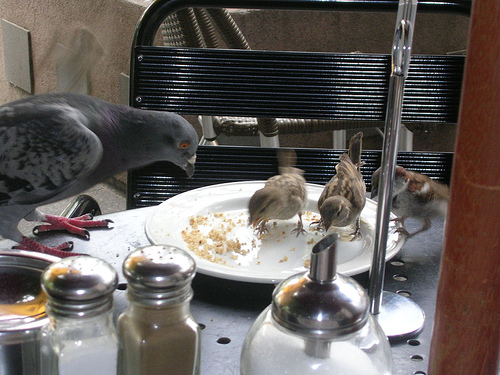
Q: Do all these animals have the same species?
A: Yes, all the animals are birds.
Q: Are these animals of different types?
A: No, all the animals are birds.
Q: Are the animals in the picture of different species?
A: No, all the animals are birds.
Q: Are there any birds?
A: Yes, there are birds.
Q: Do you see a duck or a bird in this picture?
A: Yes, there are birds.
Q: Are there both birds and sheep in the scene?
A: No, there are birds but no sheep.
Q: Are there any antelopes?
A: No, there are no antelopes.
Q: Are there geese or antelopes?
A: No, there are no antelopes or geese.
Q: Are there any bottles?
A: Yes, there is a bottle.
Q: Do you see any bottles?
A: Yes, there is a bottle.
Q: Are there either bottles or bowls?
A: Yes, there is a bottle.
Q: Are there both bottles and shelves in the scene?
A: No, there is a bottle but no shelves.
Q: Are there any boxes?
A: No, there are no boxes.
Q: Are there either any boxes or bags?
A: No, there are no boxes or bags.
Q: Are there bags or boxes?
A: No, there are no boxes or bags.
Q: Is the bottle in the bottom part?
A: Yes, the bottle is in the bottom of the image.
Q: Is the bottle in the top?
A: No, the bottle is in the bottom of the image.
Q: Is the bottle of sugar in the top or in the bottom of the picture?
A: The bottle is in the bottom of the image.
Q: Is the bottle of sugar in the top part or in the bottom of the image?
A: The bottle is in the bottom of the image.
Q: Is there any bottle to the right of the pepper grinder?
A: Yes, there is a bottle to the right of the pepper grinder.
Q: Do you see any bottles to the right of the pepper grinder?
A: Yes, there is a bottle to the right of the pepper grinder.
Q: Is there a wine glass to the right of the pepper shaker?
A: No, there is a bottle to the right of the pepper shaker.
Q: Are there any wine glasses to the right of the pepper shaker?
A: No, there is a bottle to the right of the pepper shaker.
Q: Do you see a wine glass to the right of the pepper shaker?
A: No, there is a bottle to the right of the pepper shaker.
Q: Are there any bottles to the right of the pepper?
A: Yes, there is a bottle to the right of the pepper.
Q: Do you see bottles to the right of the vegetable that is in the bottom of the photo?
A: Yes, there is a bottle to the right of the pepper.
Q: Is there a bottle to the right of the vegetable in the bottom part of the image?
A: Yes, there is a bottle to the right of the pepper.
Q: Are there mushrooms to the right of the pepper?
A: No, there is a bottle to the right of the pepper.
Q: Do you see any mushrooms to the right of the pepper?
A: No, there is a bottle to the right of the pepper.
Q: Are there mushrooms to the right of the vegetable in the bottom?
A: No, there is a bottle to the right of the pepper.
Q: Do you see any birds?
A: Yes, there is a bird.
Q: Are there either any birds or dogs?
A: Yes, there is a bird.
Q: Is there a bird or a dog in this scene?
A: Yes, there is a bird.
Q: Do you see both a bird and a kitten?
A: No, there is a bird but no kittens.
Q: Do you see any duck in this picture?
A: No, there are no ducks.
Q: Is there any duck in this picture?
A: No, there are no ducks.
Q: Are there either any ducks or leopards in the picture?
A: No, there are no ducks or leopards.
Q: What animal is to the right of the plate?
A: The animal is a bird.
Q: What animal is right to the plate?
A: The animal is a bird.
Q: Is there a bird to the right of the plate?
A: Yes, there is a bird to the right of the plate.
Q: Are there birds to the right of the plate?
A: Yes, there is a bird to the right of the plate.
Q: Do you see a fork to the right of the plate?
A: No, there is a bird to the right of the plate.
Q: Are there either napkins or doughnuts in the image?
A: No, there are no napkins or doughnuts.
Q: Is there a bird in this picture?
A: Yes, there is a bird.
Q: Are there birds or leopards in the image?
A: Yes, there is a bird.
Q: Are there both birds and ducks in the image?
A: No, there is a bird but no ducks.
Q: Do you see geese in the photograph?
A: No, there are no geese.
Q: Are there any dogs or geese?
A: No, there are no geese or dogs.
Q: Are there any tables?
A: Yes, there is a table.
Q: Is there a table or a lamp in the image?
A: Yes, there is a table.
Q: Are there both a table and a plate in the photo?
A: Yes, there are both a table and a plate.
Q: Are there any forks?
A: No, there are no forks.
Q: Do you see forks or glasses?
A: No, there are no forks or glasses.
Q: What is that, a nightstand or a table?
A: That is a table.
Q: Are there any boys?
A: No, there are no boys.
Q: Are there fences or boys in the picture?
A: No, there are no boys or fences.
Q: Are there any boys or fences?
A: No, there are no boys or fences.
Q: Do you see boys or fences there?
A: No, there are no boys or fences.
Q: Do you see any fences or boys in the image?
A: No, there are no boys or fences.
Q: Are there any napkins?
A: No, there are no napkins.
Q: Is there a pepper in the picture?
A: Yes, there is a pepper.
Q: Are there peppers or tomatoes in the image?
A: Yes, there is a pepper.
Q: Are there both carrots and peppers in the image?
A: No, there is a pepper but no carrots.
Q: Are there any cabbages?
A: No, there are no cabbages.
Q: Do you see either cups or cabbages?
A: No, there are no cabbages or cups.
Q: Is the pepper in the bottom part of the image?
A: Yes, the pepper is in the bottom of the image.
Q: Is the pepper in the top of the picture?
A: No, the pepper is in the bottom of the image.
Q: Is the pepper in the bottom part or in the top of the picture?
A: The pepper is in the bottom of the image.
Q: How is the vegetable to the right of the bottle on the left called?
A: The vegetable is a pepper.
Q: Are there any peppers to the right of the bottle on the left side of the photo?
A: Yes, there is a pepper to the right of the bottle.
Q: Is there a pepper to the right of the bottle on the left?
A: Yes, there is a pepper to the right of the bottle.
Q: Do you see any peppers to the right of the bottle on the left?
A: Yes, there is a pepper to the right of the bottle.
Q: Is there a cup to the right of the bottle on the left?
A: No, there is a pepper to the right of the bottle.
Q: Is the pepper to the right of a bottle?
A: Yes, the pepper is to the right of a bottle.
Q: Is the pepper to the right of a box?
A: No, the pepper is to the right of a bottle.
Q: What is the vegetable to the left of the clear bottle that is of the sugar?
A: The vegetable is a pepper.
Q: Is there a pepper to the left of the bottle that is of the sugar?
A: Yes, there is a pepper to the left of the bottle.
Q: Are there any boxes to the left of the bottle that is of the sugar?
A: No, there is a pepper to the left of the bottle.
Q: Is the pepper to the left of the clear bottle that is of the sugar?
A: Yes, the pepper is to the left of the bottle.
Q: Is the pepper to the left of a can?
A: No, the pepper is to the left of the bottle.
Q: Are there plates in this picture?
A: Yes, there is a plate.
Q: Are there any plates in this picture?
A: Yes, there is a plate.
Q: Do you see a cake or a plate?
A: Yes, there is a plate.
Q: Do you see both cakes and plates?
A: No, there is a plate but no cakes.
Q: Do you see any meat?
A: No, there is no meat.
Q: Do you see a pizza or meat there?
A: No, there are no meat or pizzas.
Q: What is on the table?
A: The plate is on the table.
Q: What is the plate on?
A: The plate is on the table.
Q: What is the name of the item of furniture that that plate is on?
A: The piece of furniture is a table.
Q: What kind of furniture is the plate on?
A: The plate is on the table.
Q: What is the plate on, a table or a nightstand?
A: The plate is on a table.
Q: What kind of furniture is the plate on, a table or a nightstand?
A: The plate is on a table.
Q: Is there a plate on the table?
A: Yes, there is a plate on the table.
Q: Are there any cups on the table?
A: No, there is a plate on the table.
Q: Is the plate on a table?
A: Yes, the plate is on a table.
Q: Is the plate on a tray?
A: No, the plate is on a table.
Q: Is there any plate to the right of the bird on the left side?
A: Yes, there is a plate to the right of the bird.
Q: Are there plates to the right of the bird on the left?
A: Yes, there is a plate to the right of the bird.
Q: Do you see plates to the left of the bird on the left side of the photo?
A: No, the plate is to the right of the bird.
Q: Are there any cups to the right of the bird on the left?
A: No, there is a plate to the right of the bird.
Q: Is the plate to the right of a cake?
A: No, the plate is to the right of the bird.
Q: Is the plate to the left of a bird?
A: No, the plate is to the right of a bird.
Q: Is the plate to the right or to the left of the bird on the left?
A: The plate is to the right of the bird.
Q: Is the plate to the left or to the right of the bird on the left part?
A: The plate is to the right of the bird.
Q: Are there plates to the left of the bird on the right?
A: Yes, there is a plate to the left of the bird.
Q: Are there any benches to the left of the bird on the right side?
A: No, there is a plate to the left of the bird.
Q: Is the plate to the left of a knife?
A: No, the plate is to the left of the bird.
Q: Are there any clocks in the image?
A: No, there are no clocks.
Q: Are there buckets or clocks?
A: No, there are no clocks or buckets.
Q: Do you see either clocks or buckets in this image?
A: No, there are no clocks or buckets.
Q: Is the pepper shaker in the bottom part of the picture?
A: Yes, the pepper shaker is in the bottom of the image.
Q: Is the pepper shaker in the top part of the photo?
A: No, the pepper shaker is in the bottom of the image.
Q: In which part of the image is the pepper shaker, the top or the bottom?
A: The pepper shaker is in the bottom of the image.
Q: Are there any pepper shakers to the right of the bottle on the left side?
A: Yes, there is a pepper shaker to the right of the bottle.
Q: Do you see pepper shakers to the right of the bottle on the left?
A: Yes, there is a pepper shaker to the right of the bottle.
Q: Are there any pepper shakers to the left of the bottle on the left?
A: No, the pepper shaker is to the right of the bottle.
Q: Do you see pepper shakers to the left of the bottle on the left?
A: No, the pepper shaker is to the right of the bottle.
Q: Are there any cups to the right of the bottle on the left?
A: No, there is a pepper shaker to the right of the bottle.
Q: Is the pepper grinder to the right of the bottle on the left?
A: Yes, the pepper grinder is to the right of the bottle.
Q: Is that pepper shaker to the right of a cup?
A: No, the pepper shaker is to the right of the bottle.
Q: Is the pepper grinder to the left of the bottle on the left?
A: No, the pepper grinder is to the right of the bottle.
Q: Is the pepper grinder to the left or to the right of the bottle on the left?
A: The pepper grinder is to the right of the bottle.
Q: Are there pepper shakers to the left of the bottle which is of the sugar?
A: Yes, there is a pepper shaker to the left of the bottle.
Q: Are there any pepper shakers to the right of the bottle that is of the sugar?
A: No, the pepper shaker is to the left of the bottle.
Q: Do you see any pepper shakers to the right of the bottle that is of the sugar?
A: No, the pepper shaker is to the left of the bottle.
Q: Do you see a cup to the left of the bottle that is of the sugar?
A: No, there is a pepper shaker to the left of the bottle.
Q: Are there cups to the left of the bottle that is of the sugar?
A: No, there is a pepper shaker to the left of the bottle.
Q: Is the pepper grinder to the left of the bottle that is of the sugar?
A: Yes, the pepper grinder is to the left of the bottle.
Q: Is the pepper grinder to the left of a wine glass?
A: No, the pepper grinder is to the left of the bottle.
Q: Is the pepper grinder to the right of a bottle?
A: No, the pepper grinder is to the left of a bottle.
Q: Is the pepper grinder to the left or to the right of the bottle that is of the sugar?
A: The pepper grinder is to the left of the bottle.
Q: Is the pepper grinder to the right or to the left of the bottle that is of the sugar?
A: The pepper grinder is to the left of the bottle.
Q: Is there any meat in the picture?
A: No, there is no meat.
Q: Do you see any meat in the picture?
A: No, there is no meat.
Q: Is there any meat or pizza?
A: No, there are no meat or pizzas.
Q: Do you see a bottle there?
A: Yes, there is a bottle.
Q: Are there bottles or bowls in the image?
A: Yes, there is a bottle.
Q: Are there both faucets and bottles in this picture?
A: No, there is a bottle but no faucets.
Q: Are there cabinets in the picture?
A: No, there are no cabinets.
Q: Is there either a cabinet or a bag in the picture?
A: No, there are no cabinets or bags.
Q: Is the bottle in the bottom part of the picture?
A: Yes, the bottle is in the bottom of the image.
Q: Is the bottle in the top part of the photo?
A: No, the bottle is in the bottom of the image.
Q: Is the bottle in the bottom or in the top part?
A: The bottle is in the bottom of the image.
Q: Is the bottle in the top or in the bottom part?
A: The bottle is in the bottom of the image.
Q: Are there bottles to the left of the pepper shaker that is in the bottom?
A: Yes, there is a bottle to the left of the pepper grinder.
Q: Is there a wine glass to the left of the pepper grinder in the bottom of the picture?
A: No, there is a bottle to the left of the pepper grinder.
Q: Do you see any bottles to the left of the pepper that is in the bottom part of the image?
A: Yes, there is a bottle to the left of the pepper.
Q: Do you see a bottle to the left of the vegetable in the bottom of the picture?
A: Yes, there is a bottle to the left of the pepper.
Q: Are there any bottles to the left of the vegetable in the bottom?
A: Yes, there is a bottle to the left of the pepper.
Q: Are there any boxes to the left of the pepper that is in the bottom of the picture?
A: No, there is a bottle to the left of the pepper.